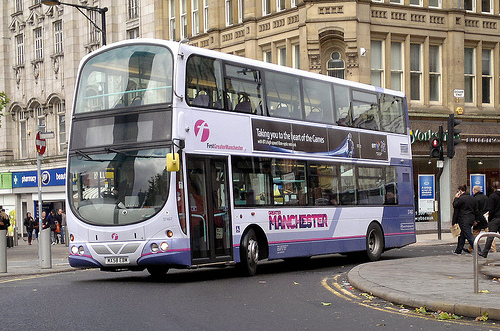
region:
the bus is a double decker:
[186, 73, 296, 233]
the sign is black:
[318, 131, 338, 144]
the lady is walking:
[448, 183, 475, 260]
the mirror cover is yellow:
[159, 149, 181, 173]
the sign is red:
[31, 126, 51, 153]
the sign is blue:
[46, 173, 61, 185]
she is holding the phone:
[455, 182, 470, 197]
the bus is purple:
[385, 209, 400, 231]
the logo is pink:
[191, 116, 209, 143]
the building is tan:
[310, 10, 345, 27]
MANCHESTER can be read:
[255, 200, 357, 235]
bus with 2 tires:
[231, 213, 399, 275]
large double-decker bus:
[85, 42, 411, 242]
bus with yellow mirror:
[146, 160, 221, 205]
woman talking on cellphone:
[434, 180, 489, 249]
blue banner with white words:
[5, 165, 76, 202]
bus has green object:
[66, 81, 203, 130]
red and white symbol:
[192, 115, 236, 161]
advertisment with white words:
[249, 114, 365, 159]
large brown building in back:
[267, 13, 487, 109]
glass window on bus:
[183, 51, 222, 109]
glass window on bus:
[222, 58, 261, 118]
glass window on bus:
[261, 68, 303, 122]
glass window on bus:
[301, 74, 335, 126]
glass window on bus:
[333, 82, 350, 126]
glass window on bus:
[349, 87, 379, 131]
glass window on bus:
[376, 92, 404, 136]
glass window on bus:
[230, 153, 271, 204]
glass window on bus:
[270, 158, 306, 205]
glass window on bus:
[304, 158, 340, 202]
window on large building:
[427, 42, 442, 103]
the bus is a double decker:
[65, 22, 422, 272]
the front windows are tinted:
[65, 47, 166, 226]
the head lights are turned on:
[71, 240, 171, 260]